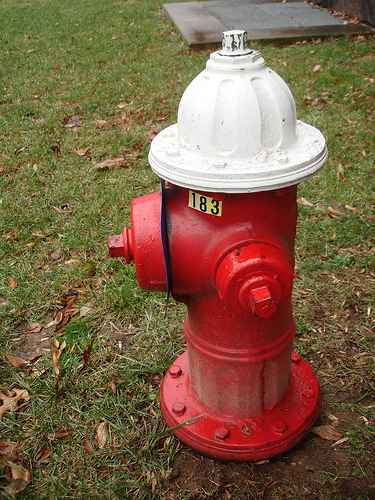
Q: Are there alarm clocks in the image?
A: No, there are no alarm clocks.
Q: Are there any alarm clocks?
A: No, there are no alarm clocks.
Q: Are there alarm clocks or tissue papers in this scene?
A: No, there are no alarm clocks or tissue papers.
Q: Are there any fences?
A: No, there are no fences.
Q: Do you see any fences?
A: No, there are no fences.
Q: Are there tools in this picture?
A: No, there are no tools.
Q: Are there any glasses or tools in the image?
A: No, there are no tools or glasses.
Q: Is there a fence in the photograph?
A: No, there are no fences.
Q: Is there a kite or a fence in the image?
A: No, there are no fences or kites.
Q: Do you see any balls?
A: No, there are no balls.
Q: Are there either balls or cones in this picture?
A: No, there are no balls or cones.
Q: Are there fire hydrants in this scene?
A: Yes, there is a fire hydrant.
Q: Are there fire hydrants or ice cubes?
A: Yes, there is a fire hydrant.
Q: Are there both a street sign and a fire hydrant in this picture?
A: No, there is a fire hydrant but no street signs.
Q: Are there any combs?
A: No, there are no combs.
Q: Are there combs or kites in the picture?
A: No, there are no combs or kites.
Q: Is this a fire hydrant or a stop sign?
A: This is a fire hydrant.